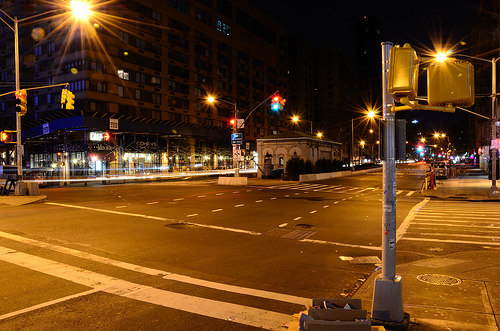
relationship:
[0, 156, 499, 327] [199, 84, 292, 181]
street has street light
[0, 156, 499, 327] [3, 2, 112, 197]
street has street light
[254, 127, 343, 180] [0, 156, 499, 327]
building in middle of street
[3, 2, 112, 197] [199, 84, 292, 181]
street light next to street light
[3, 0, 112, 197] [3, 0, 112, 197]
street light next to street light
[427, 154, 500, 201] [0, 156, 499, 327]
sidewalk next to street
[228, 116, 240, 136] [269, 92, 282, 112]
stop light next to stop light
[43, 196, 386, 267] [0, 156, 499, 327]
line on street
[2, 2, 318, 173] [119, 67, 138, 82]
building has window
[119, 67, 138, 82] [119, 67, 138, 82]
window next to window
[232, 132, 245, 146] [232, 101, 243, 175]
traffic sign hanging on pole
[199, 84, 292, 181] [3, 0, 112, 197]
street light next to street light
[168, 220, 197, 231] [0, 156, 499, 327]
sewer hole on top of street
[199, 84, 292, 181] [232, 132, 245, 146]
street light has sign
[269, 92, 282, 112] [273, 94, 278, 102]
stop light has red light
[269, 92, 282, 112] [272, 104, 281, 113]
stop light has green light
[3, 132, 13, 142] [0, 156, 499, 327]
sign hanging over street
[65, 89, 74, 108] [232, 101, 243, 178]
pedestrian signal hanging from pole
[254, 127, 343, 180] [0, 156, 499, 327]
building along street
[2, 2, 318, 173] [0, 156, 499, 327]
building along street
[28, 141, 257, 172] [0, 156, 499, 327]
shop along street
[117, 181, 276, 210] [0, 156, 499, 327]
dotted line painted on street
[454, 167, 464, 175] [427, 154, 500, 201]
box on sidewalk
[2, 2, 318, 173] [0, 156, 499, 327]
building behind street